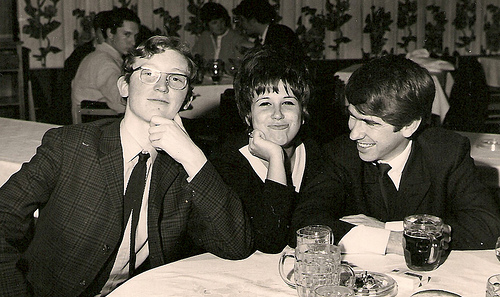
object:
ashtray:
[346, 271, 398, 296]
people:
[71, 8, 139, 119]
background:
[5, 0, 493, 126]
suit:
[0, 120, 252, 297]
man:
[0, 36, 251, 297]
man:
[292, 53, 500, 262]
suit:
[289, 127, 499, 256]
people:
[208, 49, 333, 251]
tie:
[110, 150, 158, 272]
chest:
[59, 142, 172, 239]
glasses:
[121, 63, 193, 91]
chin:
[261, 137, 295, 147]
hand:
[246, 127, 282, 157]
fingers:
[148, 131, 166, 142]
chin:
[139, 109, 166, 124]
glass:
[401, 214, 452, 271]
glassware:
[290, 221, 336, 281]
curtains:
[302, 0, 488, 59]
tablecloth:
[105, 248, 500, 296]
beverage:
[400, 227, 446, 267]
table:
[106, 245, 499, 297]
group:
[60, 0, 312, 121]